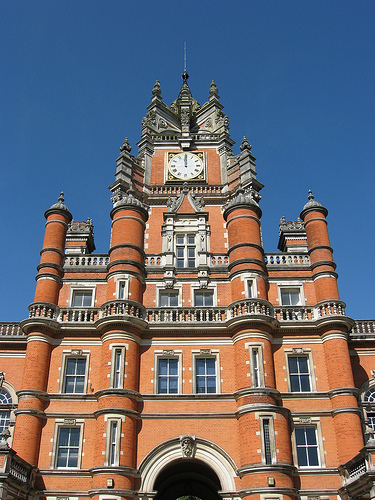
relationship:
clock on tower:
[160, 147, 204, 189] [45, 37, 312, 498]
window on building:
[149, 353, 181, 397] [54, 190, 374, 490]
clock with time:
[160, 147, 204, 189] [179, 162, 191, 170]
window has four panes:
[149, 353, 181, 397] [159, 349, 171, 376]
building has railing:
[54, 190, 374, 490] [3, 451, 44, 493]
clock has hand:
[160, 147, 204, 189] [184, 156, 191, 174]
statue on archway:
[176, 438, 199, 457] [139, 437, 243, 499]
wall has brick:
[157, 393, 271, 436] [208, 427, 219, 439]